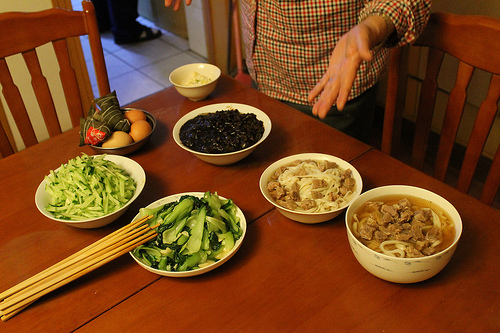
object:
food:
[33, 62, 464, 282]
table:
[0, 70, 500, 333]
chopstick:
[2, 214, 161, 318]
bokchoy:
[129, 191, 244, 272]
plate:
[126, 191, 246, 277]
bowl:
[171, 102, 271, 166]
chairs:
[380, 10, 500, 205]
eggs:
[129, 120, 153, 143]